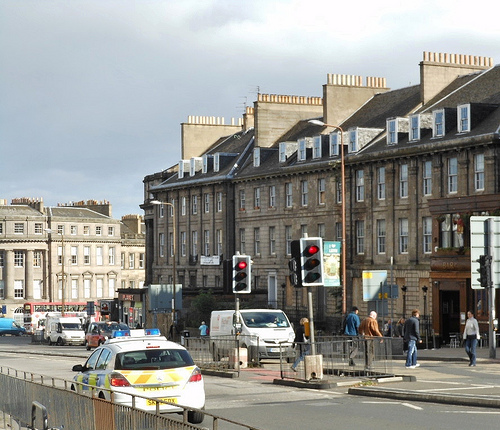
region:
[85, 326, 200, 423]
white car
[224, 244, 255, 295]
red signal light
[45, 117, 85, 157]
white clouds in blue sky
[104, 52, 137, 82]
white clouds in blue sky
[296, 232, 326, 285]
red light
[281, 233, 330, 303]
red light along a street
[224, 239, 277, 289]
red light along a street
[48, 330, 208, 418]
police car along the street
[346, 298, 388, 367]
two people walking along the street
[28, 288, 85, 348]
truck parked along the street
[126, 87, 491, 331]
tall homes along a street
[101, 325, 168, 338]
police lights on top the car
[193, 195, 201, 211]
a window on building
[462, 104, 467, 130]
a window on building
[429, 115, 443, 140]
a window on building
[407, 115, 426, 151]
a window on building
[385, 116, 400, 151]
a window on building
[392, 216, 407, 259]
a window on building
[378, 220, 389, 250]
a window on building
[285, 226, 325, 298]
traffic light on pole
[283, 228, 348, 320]
traffic light on metal pole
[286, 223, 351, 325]
pole with traffic light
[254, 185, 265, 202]
a window on a building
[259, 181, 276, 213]
a window on a building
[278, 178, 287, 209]
a window on a building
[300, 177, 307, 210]
a window on a building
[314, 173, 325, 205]
a window on a building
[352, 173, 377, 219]
a window on a building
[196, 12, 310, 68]
the cloudy sky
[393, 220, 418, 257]
windows on the building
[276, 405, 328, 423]
the street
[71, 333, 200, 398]
a car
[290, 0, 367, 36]
light in the sky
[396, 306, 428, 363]
a person walking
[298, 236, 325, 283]
a traffic signal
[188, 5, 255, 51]
the sky is grey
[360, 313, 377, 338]
person wearing a brown jacket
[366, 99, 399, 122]
roof on the building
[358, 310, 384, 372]
older man walking in a brown jacket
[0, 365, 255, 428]
rusted metal road barrier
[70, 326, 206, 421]
white and yellow police car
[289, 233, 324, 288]
black streetlight on red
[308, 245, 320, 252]
the traffic light is red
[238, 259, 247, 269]
the traffic light is red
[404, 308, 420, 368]
the man is walking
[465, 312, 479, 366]
the woman is walking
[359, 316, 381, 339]
the jacket is brown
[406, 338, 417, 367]
the jeans are blue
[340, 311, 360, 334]
the jacket is blue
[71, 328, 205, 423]
the blue lights on the car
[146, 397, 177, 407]
the license plate is yellow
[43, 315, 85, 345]
the van is white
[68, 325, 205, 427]
the compact car is white